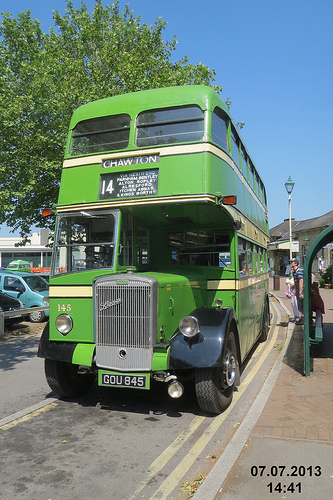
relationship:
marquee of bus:
[99, 160, 159, 196] [67, 89, 270, 385]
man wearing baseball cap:
[284, 255, 310, 324] [289, 256, 301, 265]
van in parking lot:
[2, 258, 33, 274] [5, 261, 51, 322]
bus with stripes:
[67, 89, 270, 385] [198, 282, 271, 291]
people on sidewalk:
[281, 260, 329, 324] [287, 278, 332, 421]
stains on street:
[18, 396, 89, 482] [18, 309, 259, 499]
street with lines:
[18, 309, 259, 499] [158, 412, 214, 499]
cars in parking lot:
[0, 265, 40, 322] [5, 261, 51, 322]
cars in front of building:
[0, 265, 40, 322] [13, 237, 85, 269]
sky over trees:
[157, 9, 332, 212] [16, 20, 223, 268]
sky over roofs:
[157, 9, 332, 212] [269, 219, 332, 236]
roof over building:
[280, 212, 332, 231] [275, 234, 327, 277]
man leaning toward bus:
[284, 255, 310, 324] [67, 89, 270, 385]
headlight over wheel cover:
[185, 316, 203, 337] [176, 313, 228, 365]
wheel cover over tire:
[176, 313, 228, 365] [197, 342, 260, 419]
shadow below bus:
[63, 383, 187, 428] [67, 89, 270, 385]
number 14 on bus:
[99, 174, 117, 197] [67, 89, 270, 385]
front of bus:
[63, 99, 220, 386] [67, 89, 270, 385]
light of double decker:
[57, 314, 80, 339] [55, 104, 252, 384]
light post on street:
[288, 176, 290, 292] [18, 309, 259, 499]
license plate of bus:
[101, 374, 146, 387] [67, 89, 270, 385]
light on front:
[57, 314, 80, 339] [63, 99, 220, 386]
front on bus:
[63, 99, 220, 386] [67, 89, 270, 385]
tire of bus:
[197, 342, 260, 419] [67, 89, 270, 385]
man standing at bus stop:
[284, 255, 310, 324] [296, 228, 332, 370]